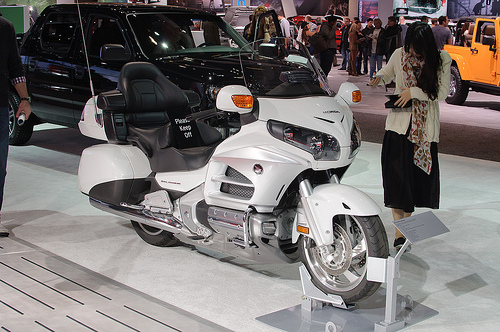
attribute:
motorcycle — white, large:
[78, 36, 388, 304]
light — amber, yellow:
[231, 94, 254, 110]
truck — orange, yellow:
[443, 16, 500, 105]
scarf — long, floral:
[402, 46, 432, 175]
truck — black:
[9, 4, 318, 146]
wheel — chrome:
[298, 183, 388, 303]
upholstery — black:
[116, 61, 223, 172]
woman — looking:
[367, 21, 452, 252]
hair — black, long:
[404, 21, 442, 101]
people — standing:
[242, 11, 451, 77]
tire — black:
[131, 220, 178, 248]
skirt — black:
[380, 113, 440, 213]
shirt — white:
[372, 46, 452, 142]